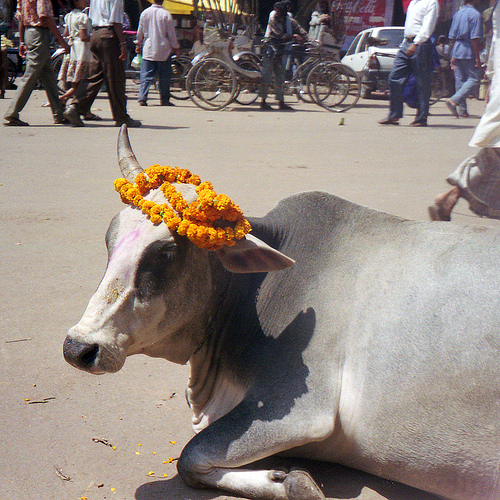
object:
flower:
[148, 201, 173, 225]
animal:
[57, 118, 499, 499]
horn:
[116, 121, 151, 199]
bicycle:
[189, 48, 375, 122]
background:
[0, 0, 499, 154]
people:
[136, 4, 180, 105]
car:
[338, 18, 434, 91]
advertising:
[322, 10, 391, 29]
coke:
[358, 4, 389, 25]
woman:
[57, 9, 99, 125]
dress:
[67, 23, 90, 63]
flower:
[335, 109, 355, 130]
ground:
[2, 110, 500, 443]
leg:
[173, 403, 334, 499]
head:
[62, 121, 296, 380]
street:
[39, 103, 449, 202]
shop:
[324, 4, 480, 94]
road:
[228, 83, 491, 232]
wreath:
[112, 164, 255, 249]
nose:
[59, 325, 108, 374]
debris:
[288, 101, 371, 156]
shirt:
[400, 4, 441, 45]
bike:
[243, 41, 393, 113]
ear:
[219, 227, 298, 285]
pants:
[81, 17, 129, 123]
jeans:
[386, 37, 435, 122]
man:
[380, 0, 439, 130]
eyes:
[131, 234, 195, 300]